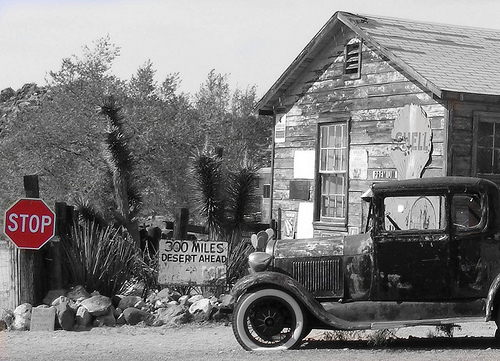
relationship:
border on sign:
[48, 207, 58, 237] [6, 191, 53, 248]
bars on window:
[316, 122, 347, 173] [313, 115, 345, 217]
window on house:
[313, 115, 345, 217] [254, 7, 497, 249]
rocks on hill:
[1, 82, 52, 137] [1, 82, 200, 227]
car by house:
[269, 181, 483, 359] [299, 24, 496, 199]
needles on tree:
[95, 92, 142, 217] [16, 34, 153, 225]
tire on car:
[223, 276, 315, 358] [230, 175, 500, 353]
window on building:
[313, 115, 346, 225] [253, 11, 498, 243]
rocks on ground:
[5, 282, 221, 329] [0, 320, 497, 359]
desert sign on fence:
[155, 239, 229, 286] [90, 222, 260, 287]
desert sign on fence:
[155, 239, 229, 286] [9, 173, 276, 313]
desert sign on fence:
[155, 239, 229, 286] [253, 224, 348, 322]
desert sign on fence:
[155, 239, 229, 286] [13, 175, 265, 304]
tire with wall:
[223, 276, 314, 351] [251, 287, 278, 293]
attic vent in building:
[344, 39, 359, 79] [253, 11, 498, 243]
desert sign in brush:
[155, 239, 229, 286] [69, 234, 282, 299]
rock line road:
[78, 294, 116, 316] [0, 318, 499, 358]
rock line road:
[118, 306, 143, 328] [0, 318, 499, 358]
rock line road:
[152, 303, 193, 326] [0, 318, 499, 358]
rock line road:
[187, 295, 215, 322] [0, 318, 499, 358]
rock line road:
[8, 299, 33, 330] [0, 318, 499, 358]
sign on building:
[331, 139, 462, 204] [252, 57, 487, 251]